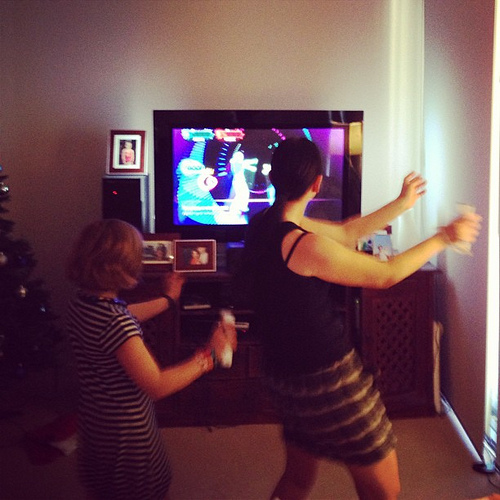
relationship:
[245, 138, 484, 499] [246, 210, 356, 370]
lady wearing tank top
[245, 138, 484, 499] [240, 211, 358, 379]
lady wearing a shirt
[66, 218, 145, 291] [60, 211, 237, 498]
hair on a girl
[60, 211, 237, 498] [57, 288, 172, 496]
girl in striped dress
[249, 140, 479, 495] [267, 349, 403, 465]
lady in skirt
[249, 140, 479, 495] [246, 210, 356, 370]
lady in tank top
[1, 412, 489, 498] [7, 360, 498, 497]
beige carpet on floor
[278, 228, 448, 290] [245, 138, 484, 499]
arm on lady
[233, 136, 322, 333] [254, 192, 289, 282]
hair in pony tail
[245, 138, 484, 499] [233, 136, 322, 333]
lady has hair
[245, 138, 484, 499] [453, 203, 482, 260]
lady has controller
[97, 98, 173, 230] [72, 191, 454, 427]
picture above media center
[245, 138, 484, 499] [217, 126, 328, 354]
lady has hair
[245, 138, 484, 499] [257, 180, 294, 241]
lady has pony tail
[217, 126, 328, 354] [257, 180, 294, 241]
hair in pony tail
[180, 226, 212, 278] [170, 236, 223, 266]
two people in frame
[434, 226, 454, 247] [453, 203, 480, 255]
strap on controller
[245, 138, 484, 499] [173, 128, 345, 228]
lady playing game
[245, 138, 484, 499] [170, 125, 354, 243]
lady playing game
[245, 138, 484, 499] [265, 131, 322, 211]
lady has head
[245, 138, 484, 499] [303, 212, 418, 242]
lady has arm